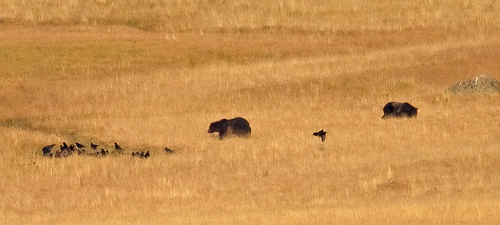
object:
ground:
[3, 2, 498, 222]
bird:
[164, 147, 173, 153]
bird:
[112, 143, 123, 151]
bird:
[41, 143, 57, 155]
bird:
[75, 142, 84, 148]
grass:
[3, 2, 496, 224]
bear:
[381, 102, 418, 119]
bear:
[207, 116, 253, 141]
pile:
[446, 75, 499, 94]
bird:
[312, 130, 326, 142]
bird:
[62, 141, 69, 148]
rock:
[443, 76, 499, 96]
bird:
[143, 151, 150, 158]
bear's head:
[207, 118, 228, 134]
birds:
[164, 146, 174, 154]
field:
[4, 5, 496, 60]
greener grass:
[9, 46, 137, 75]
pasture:
[6, 10, 484, 212]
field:
[1, 54, 499, 221]